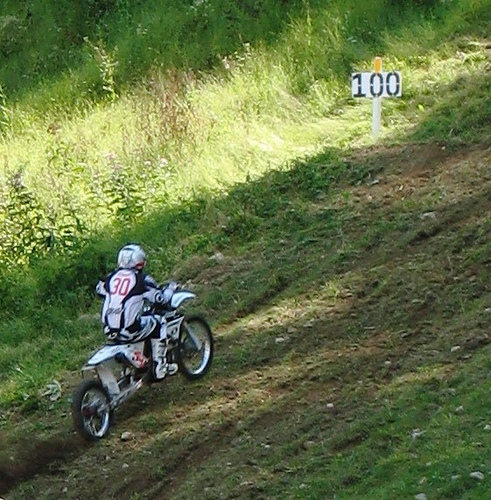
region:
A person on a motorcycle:
[52, 245, 213, 433]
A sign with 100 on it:
[350, 57, 403, 135]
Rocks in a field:
[408, 368, 480, 481]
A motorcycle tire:
[76, 380, 119, 434]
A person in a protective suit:
[100, 245, 182, 380]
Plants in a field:
[6, 180, 78, 260]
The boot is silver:
[154, 339, 182, 386]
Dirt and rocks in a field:
[364, 141, 457, 242]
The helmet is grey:
[118, 245, 149, 268]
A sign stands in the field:
[338, 52, 407, 156]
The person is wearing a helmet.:
[115, 240, 150, 273]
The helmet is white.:
[116, 242, 148, 269]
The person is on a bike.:
[67, 240, 217, 438]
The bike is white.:
[71, 292, 216, 440]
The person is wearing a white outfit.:
[92, 242, 178, 380]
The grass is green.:
[1, 0, 489, 496]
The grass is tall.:
[0, 0, 488, 394]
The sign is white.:
[344, 54, 403, 140]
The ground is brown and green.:
[4, 139, 490, 496]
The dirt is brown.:
[2, 144, 490, 493]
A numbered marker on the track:
[349, 52, 405, 147]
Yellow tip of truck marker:
[372, 47, 386, 71]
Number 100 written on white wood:
[351, 70, 404, 98]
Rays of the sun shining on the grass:
[8, 120, 305, 162]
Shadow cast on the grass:
[207, 201, 310, 282]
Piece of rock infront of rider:
[418, 209, 443, 237]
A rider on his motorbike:
[68, 240, 217, 442]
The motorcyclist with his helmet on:
[115, 240, 150, 270]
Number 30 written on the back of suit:
[108, 273, 131, 296]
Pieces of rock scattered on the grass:
[400, 388, 489, 497]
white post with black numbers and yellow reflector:
[346, 55, 407, 141]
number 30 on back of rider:
[97, 264, 139, 309]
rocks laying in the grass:
[412, 427, 489, 494]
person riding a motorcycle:
[88, 244, 184, 349]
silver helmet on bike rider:
[114, 238, 147, 275]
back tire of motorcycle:
[60, 376, 118, 439]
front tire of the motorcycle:
[167, 313, 216, 381]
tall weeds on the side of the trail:
[24, 123, 204, 219]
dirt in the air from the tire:
[10, 423, 84, 474]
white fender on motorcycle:
[80, 339, 136, 371]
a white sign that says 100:
[348, 53, 403, 136]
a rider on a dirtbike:
[66, 239, 216, 442]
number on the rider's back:
[107, 273, 131, 297]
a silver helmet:
[116, 238, 147, 273]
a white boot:
[148, 336, 178, 379]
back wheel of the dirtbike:
[67, 377, 114, 442]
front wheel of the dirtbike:
[172, 310, 216, 380]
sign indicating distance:
[348, 55, 405, 140]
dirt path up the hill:
[1, 95, 487, 497]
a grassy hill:
[1, 1, 489, 498]